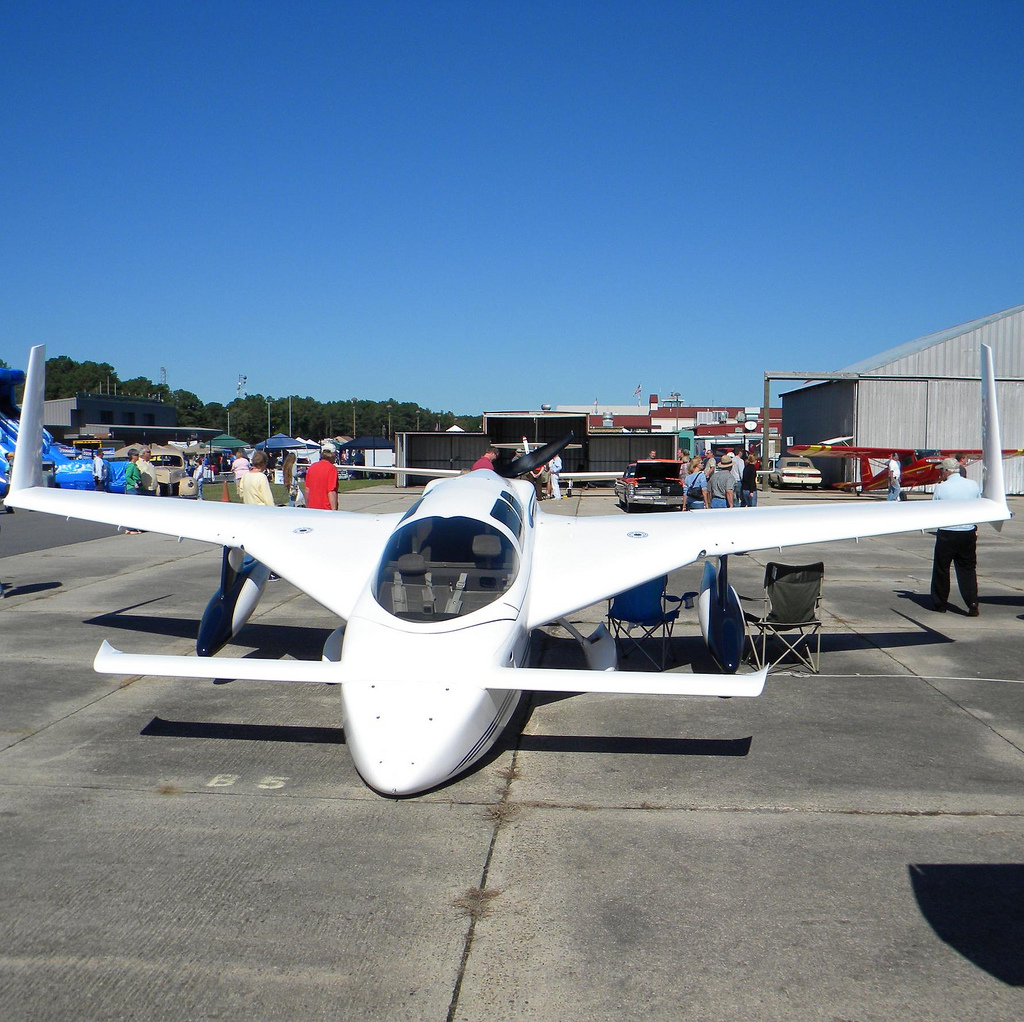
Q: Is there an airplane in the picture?
A: Yes, there is an airplane.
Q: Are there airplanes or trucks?
A: Yes, there is an airplane.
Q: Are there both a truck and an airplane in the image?
A: No, there is an airplane but no trucks.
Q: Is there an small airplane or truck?
A: Yes, there is a small airplane.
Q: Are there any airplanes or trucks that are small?
A: Yes, the airplane is small.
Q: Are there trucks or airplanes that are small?
A: Yes, the airplane is small.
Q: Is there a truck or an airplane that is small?
A: Yes, the airplane is small.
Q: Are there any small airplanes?
A: Yes, there is a small airplane.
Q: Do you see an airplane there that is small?
A: Yes, there is an airplane that is small.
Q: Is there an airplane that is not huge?
A: Yes, there is a small airplane.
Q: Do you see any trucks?
A: No, there are no trucks.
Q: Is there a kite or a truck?
A: No, there are no trucks or kites.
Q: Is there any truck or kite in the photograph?
A: No, there are no trucks or kites.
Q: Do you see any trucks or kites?
A: No, there are no trucks or kites.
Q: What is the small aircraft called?
A: The aircraft is an airplane.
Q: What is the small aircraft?
A: The aircraft is an airplane.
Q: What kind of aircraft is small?
A: The aircraft is an airplane.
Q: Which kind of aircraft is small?
A: The aircraft is an airplane.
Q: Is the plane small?
A: Yes, the plane is small.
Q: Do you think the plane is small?
A: Yes, the plane is small.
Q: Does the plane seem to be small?
A: Yes, the plane is small.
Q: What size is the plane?
A: The plane is small.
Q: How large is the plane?
A: The plane is small.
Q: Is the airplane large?
A: No, the airplane is small.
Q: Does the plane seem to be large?
A: No, the plane is small.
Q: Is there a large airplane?
A: No, there is an airplane but it is small.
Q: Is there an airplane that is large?
A: No, there is an airplane but it is small.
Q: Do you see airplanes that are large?
A: No, there is an airplane but it is small.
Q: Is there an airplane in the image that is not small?
A: No, there is an airplane but it is small.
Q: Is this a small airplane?
A: Yes, this is a small airplane.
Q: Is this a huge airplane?
A: No, this is a small airplane.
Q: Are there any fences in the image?
A: No, there are no fences.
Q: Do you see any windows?
A: Yes, there is a window.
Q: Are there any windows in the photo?
A: Yes, there is a window.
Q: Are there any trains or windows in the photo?
A: Yes, there is a window.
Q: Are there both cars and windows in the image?
A: Yes, there are both a window and a car.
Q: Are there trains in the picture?
A: No, there are no trains.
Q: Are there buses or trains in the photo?
A: No, there are no trains or buses.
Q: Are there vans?
A: No, there are no vans.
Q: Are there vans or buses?
A: No, there are no vans or buses.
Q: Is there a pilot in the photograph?
A: No, there are no pilots.